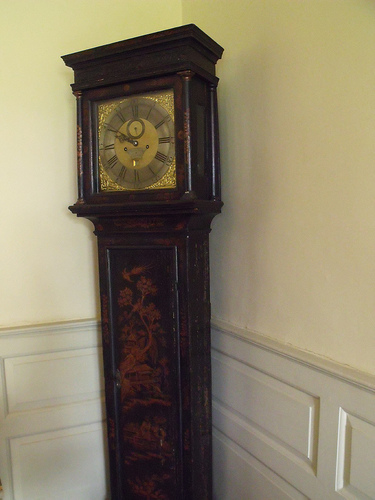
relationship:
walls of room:
[3, 3, 371, 471] [2, 5, 368, 497]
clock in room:
[73, 53, 216, 210] [2, 5, 368, 497]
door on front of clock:
[97, 240, 199, 492] [91, 86, 182, 210]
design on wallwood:
[112, 264, 178, 499] [53, 90, 367, 381]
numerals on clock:
[99, 99, 173, 187] [98, 85, 178, 191]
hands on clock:
[108, 128, 134, 144] [57, 32, 258, 499]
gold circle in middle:
[111, 117, 159, 167] [129, 136, 140, 148]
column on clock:
[178, 69, 197, 192] [95, 95, 179, 187]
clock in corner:
[91, 77, 187, 195] [173, 0, 188, 25]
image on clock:
[115, 253, 170, 497] [40, 17, 208, 213]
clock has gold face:
[91, 77, 187, 195] [92, 86, 177, 190]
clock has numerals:
[91, 77, 187, 195] [130, 102, 172, 183]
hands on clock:
[110, 126, 138, 149] [95, 95, 179, 187]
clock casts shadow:
[91, 77, 187, 195] [191, 53, 284, 498]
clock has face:
[91, 77, 187, 195] [97, 95, 178, 190]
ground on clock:
[305, 112, 334, 151] [91, 77, 187, 195]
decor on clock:
[101, 232, 193, 496] [93, 85, 210, 205]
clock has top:
[91, 77, 187, 195] [54, 21, 235, 91]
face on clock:
[97, 95, 178, 190] [91, 77, 187, 195]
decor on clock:
[101, 232, 193, 500] [65, 44, 230, 314]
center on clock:
[131, 139, 140, 146] [95, 95, 179, 187]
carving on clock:
[111, 262, 188, 498] [91, 77, 187, 195]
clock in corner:
[91, 77, 187, 195] [82, 239, 240, 490]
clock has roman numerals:
[91, 77, 187, 195] [92, 95, 175, 191]